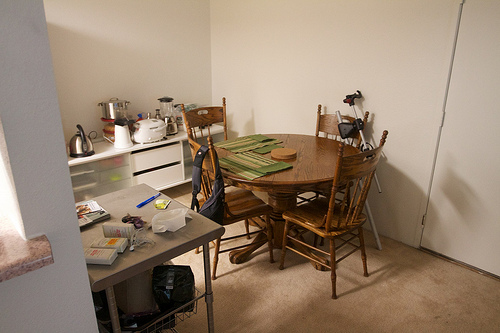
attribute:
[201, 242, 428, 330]
floor — carpeted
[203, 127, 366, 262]
table — wooden, round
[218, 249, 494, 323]
floor — brown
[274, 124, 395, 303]
chair — wooden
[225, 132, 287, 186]
placemat — green, dinner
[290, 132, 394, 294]
chair — brown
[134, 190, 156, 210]
pen — blue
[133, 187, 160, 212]
pen — blue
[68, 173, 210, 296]
counter — grey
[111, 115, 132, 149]
pitcher — white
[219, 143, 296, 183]
table mat — blue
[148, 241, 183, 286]
table — silver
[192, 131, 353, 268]
brown table — wooden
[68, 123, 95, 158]
kettle — silver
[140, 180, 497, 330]
carpet — brown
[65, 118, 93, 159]
kettle — metal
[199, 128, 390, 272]
table — brown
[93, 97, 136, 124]
pan — metal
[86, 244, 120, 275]
box — white